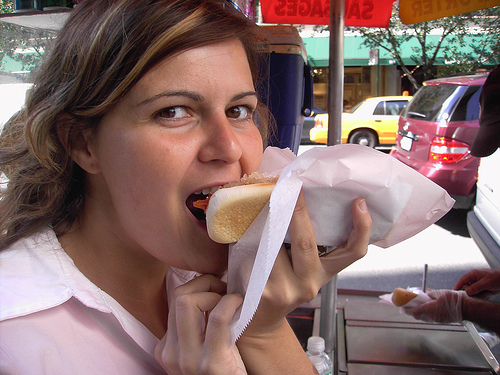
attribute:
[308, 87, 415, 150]
cab — yellow, yellow colored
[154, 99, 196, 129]
eye — hazel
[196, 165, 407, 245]
hotdog — wrapped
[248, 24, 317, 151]
cooler — blue, white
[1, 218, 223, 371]
shirt — white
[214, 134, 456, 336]
napkin — white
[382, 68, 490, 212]
van — red, maroon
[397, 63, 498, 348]
worker — preparing hotdog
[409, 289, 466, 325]
glove — plastic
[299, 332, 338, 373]
bottle — plastic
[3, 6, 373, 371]
woman — happy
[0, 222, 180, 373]
collar — pink